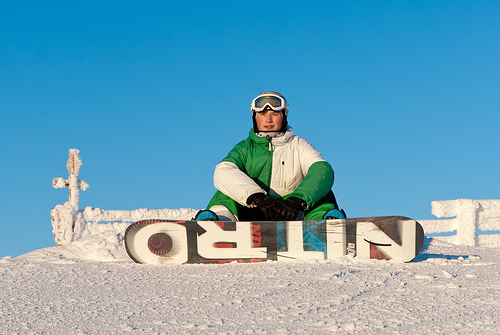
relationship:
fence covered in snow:
[98, 179, 464, 271] [105, 254, 424, 330]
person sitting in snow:
[190, 91, 346, 222] [16, 272, 498, 329]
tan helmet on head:
[259, 90, 282, 99] [249, 88, 289, 132]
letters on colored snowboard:
[131, 222, 414, 260] [124, 215, 424, 265]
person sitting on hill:
[138, 85, 376, 261] [2, 240, 498, 330]